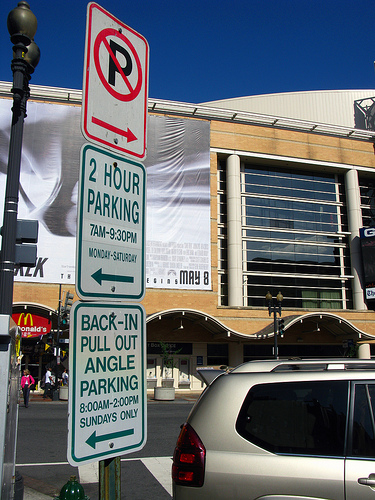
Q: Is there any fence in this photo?
A: No, there are no fences.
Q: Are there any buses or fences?
A: No, there are no fences or buses.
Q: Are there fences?
A: No, there are no fences.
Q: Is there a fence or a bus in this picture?
A: No, there are no fences or buses.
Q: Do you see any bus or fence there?
A: No, there are no fences or buses.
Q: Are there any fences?
A: No, there are no fences.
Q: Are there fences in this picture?
A: No, there are no fences.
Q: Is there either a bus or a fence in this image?
A: No, there are no fences or buses.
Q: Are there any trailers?
A: No, there are no trailers.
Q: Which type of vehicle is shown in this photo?
A: The vehicle is a car.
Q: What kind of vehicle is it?
A: The vehicle is a car.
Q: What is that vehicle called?
A: This is a car.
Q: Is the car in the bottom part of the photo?
A: Yes, the car is in the bottom of the image.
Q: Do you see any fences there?
A: No, there are no fences.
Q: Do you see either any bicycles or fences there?
A: No, there are no fences or bicycles.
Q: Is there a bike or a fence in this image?
A: No, there are no fences or bikes.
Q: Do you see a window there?
A: Yes, there are windows.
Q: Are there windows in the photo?
A: Yes, there are windows.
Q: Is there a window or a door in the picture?
A: Yes, there are windows.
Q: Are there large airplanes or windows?
A: Yes, there are large windows.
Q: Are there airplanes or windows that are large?
A: Yes, the windows are large.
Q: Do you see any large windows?
A: Yes, there are large windows.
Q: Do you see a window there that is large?
A: Yes, there are windows that are large.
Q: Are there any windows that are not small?
A: Yes, there are large windows.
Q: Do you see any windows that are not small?
A: Yes, there are large windows.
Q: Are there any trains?
A: No, there are no trains.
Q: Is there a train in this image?
A: No, there are no trains.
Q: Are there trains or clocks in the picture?
A: No, there are no trains or clocks.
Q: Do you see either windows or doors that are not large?
A: No, there are windows but they are large.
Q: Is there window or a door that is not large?
A: No, there are windows but they are large.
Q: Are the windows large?
A: Yes, the windows are large.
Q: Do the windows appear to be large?
A: Yes, the windows are large.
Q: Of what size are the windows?
A: The windows are large.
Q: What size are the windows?
A: The windows are large.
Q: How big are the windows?
A: The windows are large.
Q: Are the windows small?
A: No, the windows are large.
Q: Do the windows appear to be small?
A: No, the windows are large.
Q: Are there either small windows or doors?
A: No, there are windows but they are large.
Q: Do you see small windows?
A: No, there are windows but they are large.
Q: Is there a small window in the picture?
A: No, there are windows but they are large.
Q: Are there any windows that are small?
A: No, there are windows but they are large.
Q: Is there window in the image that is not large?
A: No, there are windows but they are large.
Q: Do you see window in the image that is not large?
A: No, there are windows but they are large.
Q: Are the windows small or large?
A: The windows are large.